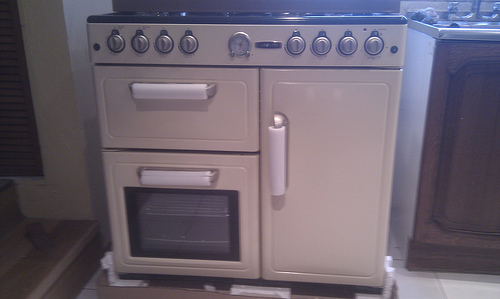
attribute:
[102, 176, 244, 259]
oven — closed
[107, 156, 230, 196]
door — glass, brown, long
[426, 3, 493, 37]
sink — silver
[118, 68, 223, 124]
handle — white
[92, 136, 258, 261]
microwave — white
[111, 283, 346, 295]
cup board — wooden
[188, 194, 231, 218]
screen — clear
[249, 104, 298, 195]
holder — rubber like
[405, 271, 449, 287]
tile — white